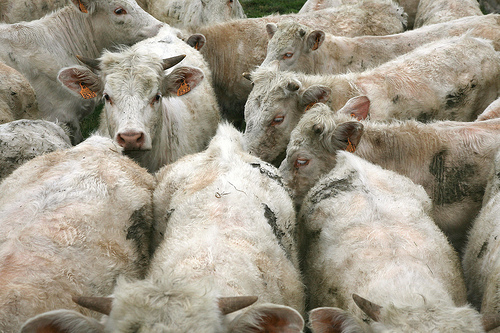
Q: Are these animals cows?
A: Yes, all the animals are cows.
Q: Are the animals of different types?
A: No, all the animals are cows.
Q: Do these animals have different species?
A: No, all the animals are cows.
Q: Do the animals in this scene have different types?
A: No, all the animals are cows.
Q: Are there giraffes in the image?
A: No, there are no giraffes.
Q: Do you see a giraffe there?
A: No, there are no giraffes.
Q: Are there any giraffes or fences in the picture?
A: No, there are no giraffes or fences.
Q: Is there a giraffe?
A: No, there are no giraffes.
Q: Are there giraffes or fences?
A: No, there are no giraffes or fences.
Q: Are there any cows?
A: Yes, there is a cow.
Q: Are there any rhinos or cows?
A: Yes, there is a cow.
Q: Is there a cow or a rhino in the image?
A: Yes, there is a cow.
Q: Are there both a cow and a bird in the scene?
A: No, there is a cow but no birds.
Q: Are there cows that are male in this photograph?
A: Yes, there is a male cow.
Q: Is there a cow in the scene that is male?
A: Yes, there is a cow that is male.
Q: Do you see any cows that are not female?
A: Yes, there is a male cow.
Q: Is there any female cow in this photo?
A: Yes, there is a female cow.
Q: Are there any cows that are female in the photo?
A: Yes, there is a female cow.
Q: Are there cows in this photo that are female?
A: Yes, there is a cow that is female.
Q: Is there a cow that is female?
A: Yes, there is a cow that is female.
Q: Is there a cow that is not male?
A: Yes, there is a female cow.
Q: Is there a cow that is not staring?
A: Yes, there is a cow that is waiting.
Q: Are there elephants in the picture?
A: No, there are no elephants.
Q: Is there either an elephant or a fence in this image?
A: No, there are no elephants or fences.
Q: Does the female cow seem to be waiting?
A: Yes, the cow is waiting.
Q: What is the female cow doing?
A: The cow is waiting.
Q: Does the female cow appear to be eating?
A: No, the cow is waiting.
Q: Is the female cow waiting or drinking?
A: The cow is waiting.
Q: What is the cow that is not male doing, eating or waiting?
A: The cow is waiting.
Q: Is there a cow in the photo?
A: Yes, there is a cow.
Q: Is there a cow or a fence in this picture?
A: Yes, there is a cow.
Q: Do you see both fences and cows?
A: No, there is a cow but no fences.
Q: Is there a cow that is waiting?
A: Yes, there is a cow that is waiting.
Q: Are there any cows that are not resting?
A: Yes, there is a cow that is waiting.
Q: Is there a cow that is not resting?
A: Yes, there is a cow that is waiting.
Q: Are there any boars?
A: No, there are no boars.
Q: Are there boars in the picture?
A: No, there are no boars.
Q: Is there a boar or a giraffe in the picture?
A: No, there are no boars or giraffes.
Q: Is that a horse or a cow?
A: That is a cow.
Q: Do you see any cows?
A: Yes, there is a cow.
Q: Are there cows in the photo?
A: Yes, there is a cow.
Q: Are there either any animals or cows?
A: Yes, there is a cow.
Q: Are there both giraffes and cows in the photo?
A: No, there is a cow but no giraffes.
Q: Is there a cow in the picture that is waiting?
A: Yes, there is a cow that is waiting.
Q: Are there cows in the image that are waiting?
A: Yes, there is a cow that is waiting.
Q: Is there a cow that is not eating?
A: Yes, there is a cow that is waiting.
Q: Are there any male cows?
A: Yes, there is a male cow.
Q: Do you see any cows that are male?
A: Yes, there is a cow that is male.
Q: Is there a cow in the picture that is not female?
A: Yes, there is a male cow.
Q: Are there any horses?
A: No, there are no horses.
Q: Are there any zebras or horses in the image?
A: No, there are no horses or zebras.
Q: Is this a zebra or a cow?
A: This is a cow.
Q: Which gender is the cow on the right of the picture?
A: The cow is male.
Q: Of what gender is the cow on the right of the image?
A: The cow is male.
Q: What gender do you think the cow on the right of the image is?
A: The cow is male.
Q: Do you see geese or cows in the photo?
A: Yes, there is a cow.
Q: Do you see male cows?
A: Yes, there is a male cow.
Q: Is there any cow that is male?
A: Yes, there is a cow that is male.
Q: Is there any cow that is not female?
A: Yes, there is a male cow.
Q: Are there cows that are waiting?
A: Yes, there is a cow that is waiting.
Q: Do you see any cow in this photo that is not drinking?
A: Yes, there is a cow that is waiting .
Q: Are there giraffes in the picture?
A: No, there are no giraffes.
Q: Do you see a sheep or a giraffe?
A: No, there are no giraffes or sheep.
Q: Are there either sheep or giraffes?
A: No, there are no giraffes or sheep.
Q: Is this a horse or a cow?
A: This is a cow.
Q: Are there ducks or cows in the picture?
A: Yes, there is a cow.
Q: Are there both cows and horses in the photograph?
A: No, there is a cow but no horses.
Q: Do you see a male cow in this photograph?
A: Yes, there is a male cow.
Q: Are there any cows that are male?
A: Yes, there is a cow that is male.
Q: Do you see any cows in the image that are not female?
A: Yes, there is a male cow.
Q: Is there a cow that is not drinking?
A: Yes, there is a cow that is waiting.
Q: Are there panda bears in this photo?
A: No, there are no panda bears.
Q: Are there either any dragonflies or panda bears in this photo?
A: No, there are no panda bears or dragonflies.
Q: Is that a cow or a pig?
A: That is a cow.